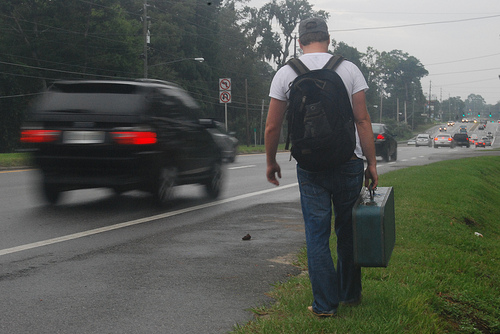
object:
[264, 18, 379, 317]
man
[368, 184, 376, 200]
handle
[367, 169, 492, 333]
area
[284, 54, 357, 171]
backpack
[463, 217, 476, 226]
hole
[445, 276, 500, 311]
grass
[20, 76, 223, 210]
car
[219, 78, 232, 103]
sign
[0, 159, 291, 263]
highway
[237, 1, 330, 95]
trees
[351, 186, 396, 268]
case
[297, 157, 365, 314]
jeans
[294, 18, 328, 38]
cap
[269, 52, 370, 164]
shirt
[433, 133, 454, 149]
cars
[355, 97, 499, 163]
background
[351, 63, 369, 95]
sleeves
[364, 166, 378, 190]
hand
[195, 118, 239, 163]
vehicle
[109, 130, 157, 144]
lights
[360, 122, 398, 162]
prius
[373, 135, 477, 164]
road